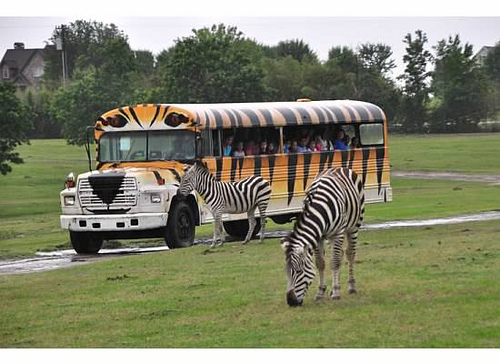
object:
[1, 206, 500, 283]
path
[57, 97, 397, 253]
bus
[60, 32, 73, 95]
pole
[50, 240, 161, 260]
puddle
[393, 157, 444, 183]
ground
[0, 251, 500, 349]
grass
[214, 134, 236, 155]
kids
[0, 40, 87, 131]
house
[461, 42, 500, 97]
house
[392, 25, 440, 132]
tree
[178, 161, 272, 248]
zebra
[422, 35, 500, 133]
tree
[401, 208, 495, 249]
ground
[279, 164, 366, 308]
zebra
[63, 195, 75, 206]
headlights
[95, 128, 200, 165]
windshield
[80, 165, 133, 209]
nose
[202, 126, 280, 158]
windows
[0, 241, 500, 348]
field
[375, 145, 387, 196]
black stripes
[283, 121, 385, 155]
bus window